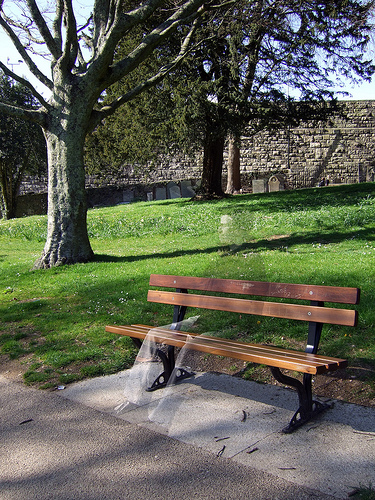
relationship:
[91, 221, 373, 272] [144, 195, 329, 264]
shadow on grass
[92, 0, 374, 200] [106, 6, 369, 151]
tree covered in leaves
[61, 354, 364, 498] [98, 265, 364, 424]
pavement underneath bench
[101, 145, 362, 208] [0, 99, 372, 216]
gravestones in front of wall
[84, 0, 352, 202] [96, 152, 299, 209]
tree net to gravestones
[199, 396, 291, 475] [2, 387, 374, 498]
sticks on ground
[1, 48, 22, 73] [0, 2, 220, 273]
street light behind tree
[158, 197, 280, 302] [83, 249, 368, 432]
ghost on bench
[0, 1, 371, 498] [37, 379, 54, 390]
park with green grass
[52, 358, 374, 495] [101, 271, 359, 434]
slab under bench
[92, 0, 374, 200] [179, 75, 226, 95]
tree with leaves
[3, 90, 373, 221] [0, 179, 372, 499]
wall in park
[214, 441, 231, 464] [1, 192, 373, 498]
debris on ground